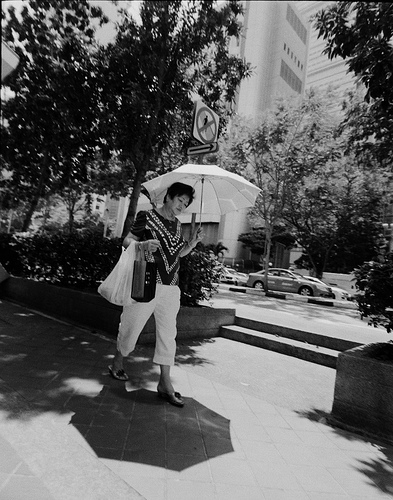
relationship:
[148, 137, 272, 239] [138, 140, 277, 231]
shadow of umbrella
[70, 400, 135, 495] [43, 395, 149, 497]
lines on ground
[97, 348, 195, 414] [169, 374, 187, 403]
shoes have design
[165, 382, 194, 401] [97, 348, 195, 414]
flower on shoes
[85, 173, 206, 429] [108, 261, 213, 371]
woman wearing cargo pants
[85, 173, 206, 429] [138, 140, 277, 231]
woman holding umbrella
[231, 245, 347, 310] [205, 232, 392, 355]
car in lot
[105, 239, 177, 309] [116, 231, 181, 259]
bag on forearm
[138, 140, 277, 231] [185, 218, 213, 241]
umbrella in hand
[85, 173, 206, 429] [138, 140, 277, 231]
woman using umbrella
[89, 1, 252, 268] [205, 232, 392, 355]
tree next to sidewalk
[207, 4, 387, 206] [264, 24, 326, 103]
building with many stories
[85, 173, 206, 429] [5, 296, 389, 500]
woman on street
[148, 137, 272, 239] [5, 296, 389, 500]
shadow on ground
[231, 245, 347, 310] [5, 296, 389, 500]
cars on street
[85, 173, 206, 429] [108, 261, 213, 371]
woman wearing pants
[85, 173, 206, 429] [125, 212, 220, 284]
woman wearing top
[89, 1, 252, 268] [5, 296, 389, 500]
tres next to street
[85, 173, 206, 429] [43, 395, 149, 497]
woman looking at ground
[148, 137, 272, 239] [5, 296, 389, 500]
shadow on pavement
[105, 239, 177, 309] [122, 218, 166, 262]
bag on arm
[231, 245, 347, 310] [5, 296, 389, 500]
cars in street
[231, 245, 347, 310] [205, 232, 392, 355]
cars in traffic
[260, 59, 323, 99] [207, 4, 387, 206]
windows on skyscraper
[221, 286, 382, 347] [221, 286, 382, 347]
sidewalk next to sidewalk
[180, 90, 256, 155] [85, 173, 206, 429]
sign above woman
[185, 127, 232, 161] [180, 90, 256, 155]
arrow on sign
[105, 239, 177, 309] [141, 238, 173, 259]
bag on wrist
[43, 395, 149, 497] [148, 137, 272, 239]
ground has shadow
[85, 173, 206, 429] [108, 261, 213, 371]
woman wearing capris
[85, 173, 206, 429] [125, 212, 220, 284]
woman wearing shirt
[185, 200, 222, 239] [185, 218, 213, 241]
post in hand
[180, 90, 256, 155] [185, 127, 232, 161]
sign above arrow